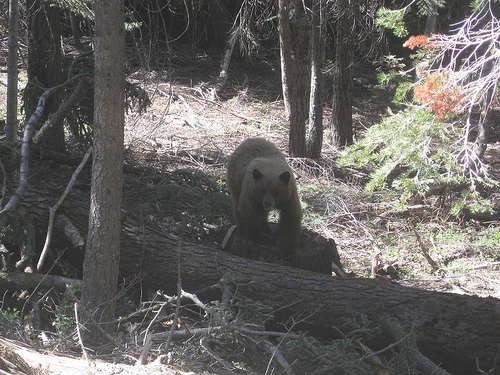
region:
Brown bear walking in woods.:
[223, 136, 309, 251]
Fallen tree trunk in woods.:
[121, 218, 498, 330]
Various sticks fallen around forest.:
[142, 285, 397, 372]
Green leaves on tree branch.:
[338, 92, 498, 202]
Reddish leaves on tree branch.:
[400, 37, 464, 119]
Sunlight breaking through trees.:
[144, 75, 281, 142]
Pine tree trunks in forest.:
[267, 4, 327, 161]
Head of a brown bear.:
[250, 168, 292, 210]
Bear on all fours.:
[228, 131, 302, 251]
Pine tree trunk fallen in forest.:
[122, 218, 497, 355]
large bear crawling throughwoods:
[218, 134, 308, 258]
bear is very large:
[221, 132, 305, 262]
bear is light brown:
[218, 126, 306, 266]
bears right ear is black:
[248, 168, 262, 185]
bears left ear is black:
[276, 168, 293, 188]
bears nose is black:
[262, 197, 274, 210]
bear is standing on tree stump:
[209, 206, 344, 283]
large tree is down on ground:
[0, 156, 497, 374]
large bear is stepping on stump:
[215, 129, 319, 260]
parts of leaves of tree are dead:
[410, 27, 467, 136]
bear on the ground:
[220, 125, 305, 239]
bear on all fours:
[218, 133, 324, 244]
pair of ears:
[249, 161, 299, 184]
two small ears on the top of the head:
[248, 163, 298, 183]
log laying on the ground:
[111, 215, 493, 363]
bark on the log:
[111, 216, 492, 358]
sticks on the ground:
[57, 282, 476, 370]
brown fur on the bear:
[221, 135, 319, 253]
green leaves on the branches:
[330, 90, 496, 215]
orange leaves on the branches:
[402, 73, 470, 114]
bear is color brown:
[211, 127, 316, 260]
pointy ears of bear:
[247, 163, 298, 193]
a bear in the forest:
[112, 71, 454, 354]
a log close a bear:
[102, 124, 492, 374]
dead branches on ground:
[31, 81, 433, 373]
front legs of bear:
[233, 208, 307, 245]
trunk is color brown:
[63, 3, 144, 327]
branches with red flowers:
[388, 10, 498, 183]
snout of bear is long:
[260, 203, 287, 233]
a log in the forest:
[111, 219, 499, 365]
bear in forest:
[209, 128, 320, 261]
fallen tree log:
[127, 213, 498, 365]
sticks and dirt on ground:
[350, 235, 424, 282]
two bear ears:
[248, 163, 294, 187]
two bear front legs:
[236, 196, 307, 265]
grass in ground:
[463, 220, 498, 253]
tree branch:
[21, 148, 88, 277]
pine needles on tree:
[364, 168, 394, 198]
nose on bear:
[260, 196, 272, 206]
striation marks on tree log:
[256, 270, 311, 295]